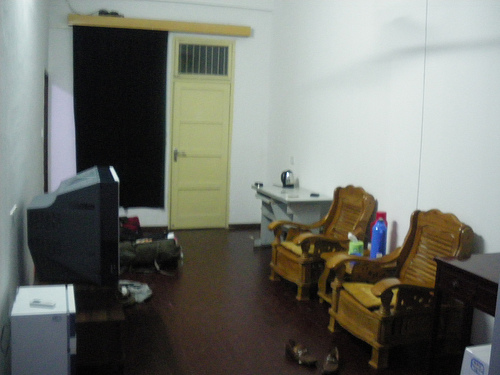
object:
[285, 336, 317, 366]
shoes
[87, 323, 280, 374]
floor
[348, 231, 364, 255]
tissues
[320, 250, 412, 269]
table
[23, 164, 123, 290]
tv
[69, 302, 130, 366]
stand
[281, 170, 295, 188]
coffee pot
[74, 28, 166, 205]
curtains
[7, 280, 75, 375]
refrigerator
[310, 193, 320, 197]
phone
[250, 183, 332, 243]
desk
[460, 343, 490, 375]
white box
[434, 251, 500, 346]
table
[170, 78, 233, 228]
door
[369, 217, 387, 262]
bottle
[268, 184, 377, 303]
chair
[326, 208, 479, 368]
chair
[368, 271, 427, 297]
arm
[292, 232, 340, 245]
arm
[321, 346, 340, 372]
shoe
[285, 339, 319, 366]
shoe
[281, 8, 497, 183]
wall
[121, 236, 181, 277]
duffle bag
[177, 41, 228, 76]
vent